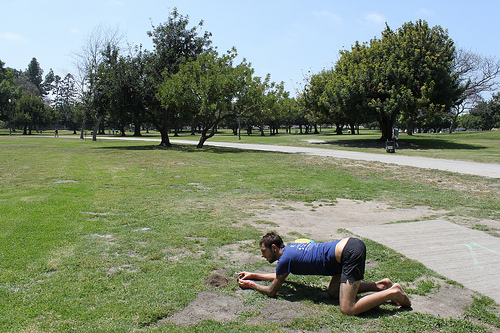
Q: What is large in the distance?
A: Trees.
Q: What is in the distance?
A: Green tree.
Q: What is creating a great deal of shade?
A: Trees.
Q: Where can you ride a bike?
A: On the pathway.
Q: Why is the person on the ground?
A: Looking for something.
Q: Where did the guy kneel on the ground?
A: On the grass.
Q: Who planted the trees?
A: The gardner.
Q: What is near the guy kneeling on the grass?
A: Wooden walkway.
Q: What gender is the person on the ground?
A: Male.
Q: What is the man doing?
A: Crawling.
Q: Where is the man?
A: Park.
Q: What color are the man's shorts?
A: Black.